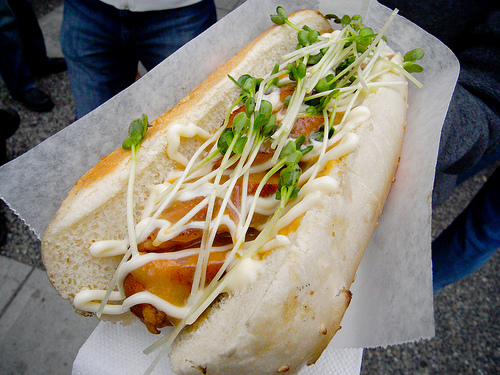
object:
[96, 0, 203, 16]
shirt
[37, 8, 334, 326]
bun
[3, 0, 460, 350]
paper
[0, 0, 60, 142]
man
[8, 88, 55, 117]
shoe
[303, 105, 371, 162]
toppings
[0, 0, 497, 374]
walkway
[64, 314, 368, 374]
paper towel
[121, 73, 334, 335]
wiener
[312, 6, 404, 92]
sprouts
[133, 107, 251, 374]
sprouts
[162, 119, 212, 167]
mayonaise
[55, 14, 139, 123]
legs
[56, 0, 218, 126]
man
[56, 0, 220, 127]
jeans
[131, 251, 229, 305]
cheese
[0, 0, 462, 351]
holder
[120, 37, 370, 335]
dog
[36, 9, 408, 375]
hot dog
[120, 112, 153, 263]
garnish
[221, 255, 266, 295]
topping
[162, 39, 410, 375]
bun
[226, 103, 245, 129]
ketchup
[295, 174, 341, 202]
mustard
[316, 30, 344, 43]
toppings